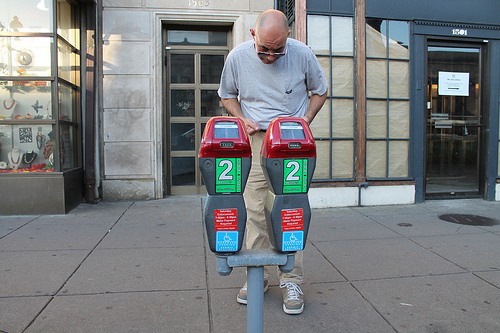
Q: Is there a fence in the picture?
A: No, there are no fences.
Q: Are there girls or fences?
A: No, there are no fences or girls.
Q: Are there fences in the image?
A: No, there are no fences.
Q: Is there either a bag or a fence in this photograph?
A: No, there are no fences or bags.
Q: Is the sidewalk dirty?
A: Yes, the sidewalk is dirty.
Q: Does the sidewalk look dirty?
A: Yes, the sidewalk is dirty.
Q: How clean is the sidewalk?
A: The sidewalk is dirty.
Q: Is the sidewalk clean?
A: No, the sidewalk is dirty.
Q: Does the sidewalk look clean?
A: No, the sidewalk is dirty.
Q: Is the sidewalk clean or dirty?
A: The sidewalk is dirty.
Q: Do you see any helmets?
A: No, there are no helmets.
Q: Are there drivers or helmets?
A: No, there are no helmets or drivers.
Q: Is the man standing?
A: Yes, the man is standing.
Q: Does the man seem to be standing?
A: Yes, the man is standing.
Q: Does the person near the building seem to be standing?
A: Yes, the man is standing.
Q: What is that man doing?
A: The man is standing.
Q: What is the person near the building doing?
A: The man is standing.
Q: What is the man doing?
A: The man is standing.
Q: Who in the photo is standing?
A: The man is standing.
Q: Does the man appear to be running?
A: No, the man is standing.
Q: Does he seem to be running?
A: No, the man is standing.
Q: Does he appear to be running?
A: No, the man is standing.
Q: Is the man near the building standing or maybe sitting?
A: The man is standing.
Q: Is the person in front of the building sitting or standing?
A: The man is standing.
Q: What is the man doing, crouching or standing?
A: The man is standing.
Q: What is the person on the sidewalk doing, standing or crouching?
A: The man is standing.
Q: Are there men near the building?
A: Yes, there is a man near the building.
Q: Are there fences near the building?
A: No, there is a man near the building.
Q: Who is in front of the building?
A: The man is in front of the building.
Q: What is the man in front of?
A: The man is in front of the building.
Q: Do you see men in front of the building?
A: Yes, there is a man in front of the building.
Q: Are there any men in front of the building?
A: Yes, there is a man in front of the building.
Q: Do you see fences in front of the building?
A: No, there is a man in front of the building.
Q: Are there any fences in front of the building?
A: No, there is a man in front of the building.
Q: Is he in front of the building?
A: Yes, the man is in front of the building.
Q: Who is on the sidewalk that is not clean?
A: The man is on the sidewalk.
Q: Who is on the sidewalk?
A: The man is on the sidewalk.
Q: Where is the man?
A: The man is on the side walk.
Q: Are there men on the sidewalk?
A: Yes, there is a man on the sidewalk.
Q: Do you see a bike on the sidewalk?
A: No, there is a man on the sidewalk.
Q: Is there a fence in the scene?
A: No, there are no fences.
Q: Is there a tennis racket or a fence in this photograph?
A: No, there are no fences or rackets.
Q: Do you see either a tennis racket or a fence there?
A: No, there are no fences or rackets.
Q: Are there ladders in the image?
A: No, there are no ladders.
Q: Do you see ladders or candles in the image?
A: No, there are no ladders or candles.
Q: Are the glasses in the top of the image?
A: Yes, the glasses are in the top of the image.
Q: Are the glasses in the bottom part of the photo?
A: No, the glasses are in the top of the image.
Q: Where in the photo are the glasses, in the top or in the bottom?
A: The glasses are in the top of the image.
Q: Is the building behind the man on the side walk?
A: Yes, the building is behind the man.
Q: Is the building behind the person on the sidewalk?
A: Yes, the building is behind the man.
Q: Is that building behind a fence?
A: No, the building is behind the man.